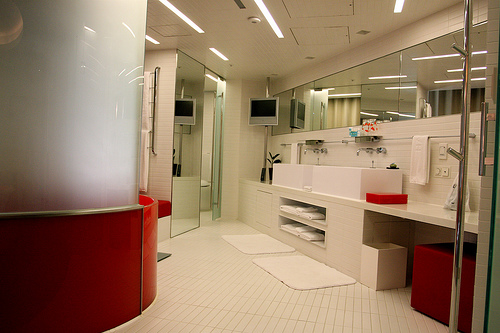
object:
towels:
[279, 202, 327, 220]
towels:
[406, 134, 431, 186]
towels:
[138, 129, 151, 194]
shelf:
[279, 225, 325, 252]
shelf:
[344, 130, 382, 142]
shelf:
[304, 139, 326, 146]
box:
[366, 192, 409, 205]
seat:
[409, 241, 476, 331]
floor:
[253, 252, 358, 291]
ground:
[357, 317, 426, 325]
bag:
[441, 170, 471, 214]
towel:
[406, 132, 430, 187]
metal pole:
[447, 1, 480, 331]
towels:
[279, 223, 325, 245]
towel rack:
[149, 56, 160, 163]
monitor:
[248, 98, 280, 127]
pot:
[267, 167, 274, 182]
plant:
[266, 143, 282, 168]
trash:
[359, 243, 409, 293]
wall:
[0, 206, 140, 331]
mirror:
[171, 48, 205, 239]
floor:
[101, 218, 462, 331]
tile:
[326, 294, 340, 306]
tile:
[255, 299, 272, 316]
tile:
[156, 319, 177, 331]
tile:
[360, 312, 369, 331]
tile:
[313, 320, 323, 331]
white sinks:
[269, 160, 312, 189]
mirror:
[270, 21, 488, 136]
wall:
[239, 5, 491, 202]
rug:
[250, 254, 356, 293]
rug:
[221, 231, 297, 256]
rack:
[280, 133, 475, 146]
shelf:
[278, 208, 326, 237]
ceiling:
[147, 1, 483, 83]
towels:
[138, 67, 152, 131]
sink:
[310, 164, 403, 201]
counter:
[241, 176, 477, 236]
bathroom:
[2, 2, 498, 332]